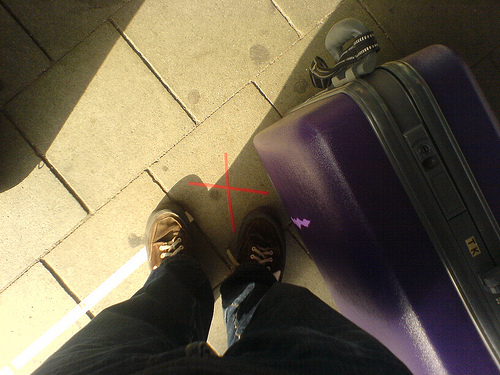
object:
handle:
[325, 17, 379, 86]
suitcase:
[251, 16, 500, 375]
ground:
[0, 0, 500, 375]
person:
[27, 203, 397, 375]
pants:
[27, 255, 407, 374]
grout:
[2, 110, 89, 215]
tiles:
[0, 0, 499, 374]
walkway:
[2, 0, 495, 375]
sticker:
[465, 236, 481, 257]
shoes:
[145, 208, 285, 282]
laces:
[153, 231, 274, 264]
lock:
[414, 143, 431, 156]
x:
[189, 152, 269, 233]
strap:
[309, 31, 380, 88]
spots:
[188, 44, 308, 105]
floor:
[0, 0, 500, 373]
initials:
[468, 238, 479, 255]